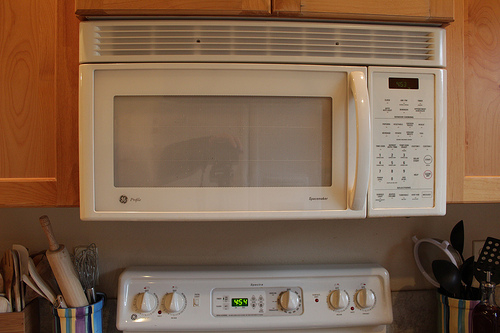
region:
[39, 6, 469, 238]
a white microwave over a stove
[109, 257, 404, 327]
the control knobs for a stove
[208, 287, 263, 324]
digital clock on a stove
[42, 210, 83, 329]
wooden rolling pin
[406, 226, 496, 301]
several cooking untensils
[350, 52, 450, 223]
push button controls for a microwave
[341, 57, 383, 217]
white door handle on a microwave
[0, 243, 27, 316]
a wooden fork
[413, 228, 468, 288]
a metal strainer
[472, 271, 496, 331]
a brown bottle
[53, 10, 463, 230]
a microwave color white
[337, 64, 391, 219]
handle of microwave is long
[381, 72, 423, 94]
screen of microwave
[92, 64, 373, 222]
door of microwave has glass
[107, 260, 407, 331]
controls of a stove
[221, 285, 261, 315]
screen of teome with the time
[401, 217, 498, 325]
container with kitchen utensils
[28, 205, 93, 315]
a roller on left side of stove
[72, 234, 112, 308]
hand blender next to roller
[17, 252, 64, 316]
spatulas behind a roller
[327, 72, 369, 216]
white handle of microwave door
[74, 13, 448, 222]
white microwave above oven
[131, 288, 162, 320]
white knob on oven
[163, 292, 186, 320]
white knob on oven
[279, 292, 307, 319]
white knob on oven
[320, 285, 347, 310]
white knob on oven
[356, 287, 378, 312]
white knob on oven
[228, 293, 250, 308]
clock on white oven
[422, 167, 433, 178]
button on white microwave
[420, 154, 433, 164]
button on white microwave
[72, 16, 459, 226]
white microwave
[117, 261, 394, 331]
five white stove knobs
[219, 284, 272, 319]
clock with 4:54 time on it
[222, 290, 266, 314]
digital clock with green numbers on it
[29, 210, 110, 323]
wooden rolling pin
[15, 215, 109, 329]
container holding kitchen utensils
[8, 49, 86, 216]
light kitchen door cabinets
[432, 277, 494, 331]
stainless steel container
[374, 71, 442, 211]
digital buttons on a microwave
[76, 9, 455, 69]
white microwave ventilation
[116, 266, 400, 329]
controls to a white kitchen stove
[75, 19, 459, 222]
built in white microwave in kitchen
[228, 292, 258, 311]
digital clock on front of stove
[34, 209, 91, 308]
wooden rolling pin in kitchen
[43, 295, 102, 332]
colorful stripped canister in kitchen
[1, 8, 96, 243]
brown wooden cabinet door in kitchen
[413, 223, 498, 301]
container full of kitchen utensils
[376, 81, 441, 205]
control panel for microwave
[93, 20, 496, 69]
vents on fron tof microwave oven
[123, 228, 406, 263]
white back splash behind oven